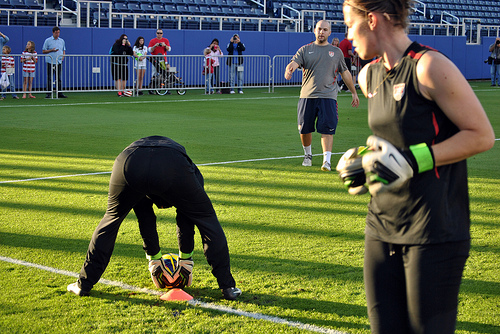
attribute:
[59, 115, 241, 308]
person — leaning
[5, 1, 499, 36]
stands — empty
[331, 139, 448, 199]
glove — white, green, black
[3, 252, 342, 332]
line — white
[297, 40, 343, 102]
t-shirt — gray 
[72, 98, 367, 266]
field — green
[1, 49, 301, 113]
fence — metal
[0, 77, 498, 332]
stadium field — blue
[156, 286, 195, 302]
cone — orange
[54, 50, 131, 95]
gate — gray 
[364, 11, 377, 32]
ear — woman's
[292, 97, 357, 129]
shorts — blue 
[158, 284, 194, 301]
cone — plastic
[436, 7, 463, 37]
handrail — white